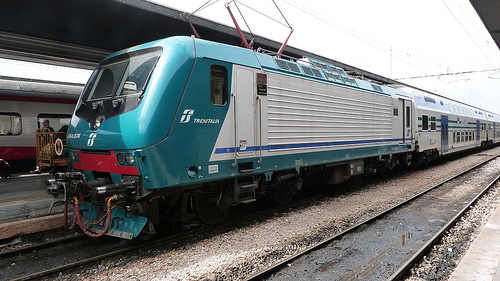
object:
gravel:
[199, 229, 289, 249]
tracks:
[282, 242, 452, 279]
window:
[431, 115, 437, 130]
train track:
[246, 155, 500, 281]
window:
[209, 65, 227, 107]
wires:
[182, 0, 297, 29]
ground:
[342, 119, 395, 145]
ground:
[255, 66, 325, 114]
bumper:
[40, 167, 158, 219]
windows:
[453, 131, 475, 144]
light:
[115, 153, 134, 166]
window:
[0, 110, 22, 135]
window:
[422, 114, 428, 130]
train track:
[2, 202, 269, 280]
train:
[47, 30, 487, 211]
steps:
[231, 177, 258, 204]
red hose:
[72, 196, 114, 237]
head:
[42, 119, 50, 127]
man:
[39, 119, 55, 133]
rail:
[256, 95, 263, 165]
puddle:
[391, 231, 422, 248]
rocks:
[60, 143, 498, 281]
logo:
[179, 104, 229, 130]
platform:
[0, 148, 85, 242]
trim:
[73, 149, 141, 175]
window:
[257, 73, 267, 93]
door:
[235, 65, 259, 155]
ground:
[0, 145, 498, 277]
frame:
[219, 0, 253, 51]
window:
[78, 46, 163, 102]